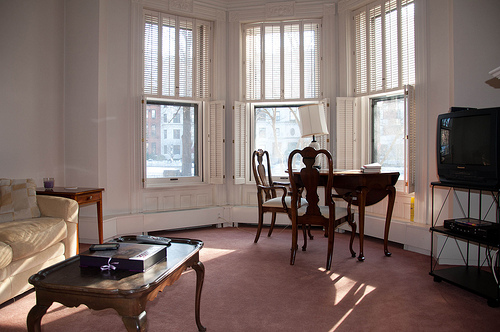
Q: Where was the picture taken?
A: In a living room.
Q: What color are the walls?
A: White.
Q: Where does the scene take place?
A: In a living room.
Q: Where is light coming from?
A: Windows.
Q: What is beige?
A: Couch.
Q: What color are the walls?
A: White.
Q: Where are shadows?
A: On the floor.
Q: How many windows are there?
A: Three.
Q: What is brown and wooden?
A: Coffee table.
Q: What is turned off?
A: TV.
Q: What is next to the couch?
A: Side table.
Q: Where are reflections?
A: On TV screen.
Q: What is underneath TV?
A: Cable box.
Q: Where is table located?
A: In front of window.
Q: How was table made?
A: By a carpenter.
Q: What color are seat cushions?
A: White.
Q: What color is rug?
A: Pink.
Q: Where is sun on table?
A: On the top.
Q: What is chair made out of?
A: Wood.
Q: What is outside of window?
A: Building.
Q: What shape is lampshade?
A: Rectangle.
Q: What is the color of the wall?
A: White.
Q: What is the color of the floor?
A: Red.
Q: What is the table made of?
A: Wood.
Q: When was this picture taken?
A: Daytime.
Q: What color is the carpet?
A: Salmon.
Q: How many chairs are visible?
A: Two.